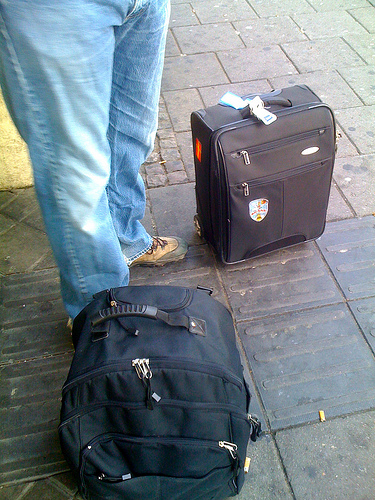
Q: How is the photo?
A: Clear.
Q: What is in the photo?
A: Bags.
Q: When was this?
A: Daytime.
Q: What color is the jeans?
A: Blue.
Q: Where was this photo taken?
A: At the airport.